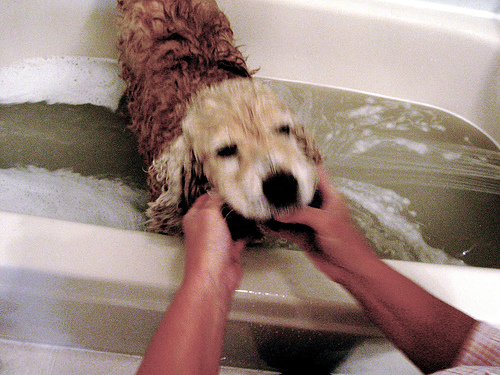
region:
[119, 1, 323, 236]
A wet dog.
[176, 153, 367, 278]
Man scrubing his dog.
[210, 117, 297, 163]
The eyes of a dog.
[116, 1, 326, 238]
The dog is white and brown.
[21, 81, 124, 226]
The soapy bath water.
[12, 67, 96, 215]
The dirty brown water.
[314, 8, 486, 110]
The bath tub is white.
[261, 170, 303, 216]
The brown nose of dog.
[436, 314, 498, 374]
A shirt in the corner.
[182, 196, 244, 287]
The hand of a person.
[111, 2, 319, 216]
the wet dog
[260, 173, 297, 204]
the dogs black nose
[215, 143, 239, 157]
the dogs right eye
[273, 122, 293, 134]
the dogs left eye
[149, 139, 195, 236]
the dogs right ear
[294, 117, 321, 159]
the dogs left ear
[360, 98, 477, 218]
the dirty bath water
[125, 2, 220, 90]
the dogs wet back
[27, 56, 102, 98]
the soapy foam in the bath water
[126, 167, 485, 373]
the persons arms bathing the dog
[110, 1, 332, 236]
dog standing in the bathtub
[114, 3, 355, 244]
dog getting a bat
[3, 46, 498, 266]
dirty bath water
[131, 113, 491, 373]
person giving the dog a bath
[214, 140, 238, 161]
tiny black eye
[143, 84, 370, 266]
hands rubbing the dog's head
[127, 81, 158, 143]
long and curly brown hair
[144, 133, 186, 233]
curly white ears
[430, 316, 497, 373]
red and white sleeve rolled up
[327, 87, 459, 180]
white swirls in the bath water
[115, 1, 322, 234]
a cute dog in the bathtub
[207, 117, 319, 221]
look at that happy face!!!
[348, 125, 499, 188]
the water spraying into the tub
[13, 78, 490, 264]
the dirty, soapy water in the tub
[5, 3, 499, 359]
the white bathtub in the room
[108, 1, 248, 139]
the wet dog body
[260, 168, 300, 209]
the dogs nose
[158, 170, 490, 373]
the arms of the man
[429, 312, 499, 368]
the shirt of the man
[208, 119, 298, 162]
the dogs closed eyes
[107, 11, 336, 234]
dog getting a bath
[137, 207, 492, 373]
person giving dog a bath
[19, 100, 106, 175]
dirty bath water from dog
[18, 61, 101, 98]
soap bubbles in bath tub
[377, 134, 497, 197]
water spray in bath tub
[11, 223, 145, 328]
white bath tub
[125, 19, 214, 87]
wet fur of a dog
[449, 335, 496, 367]
orange and white plaid shirt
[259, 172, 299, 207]
black nose of a dog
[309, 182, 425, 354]
right hand and arm